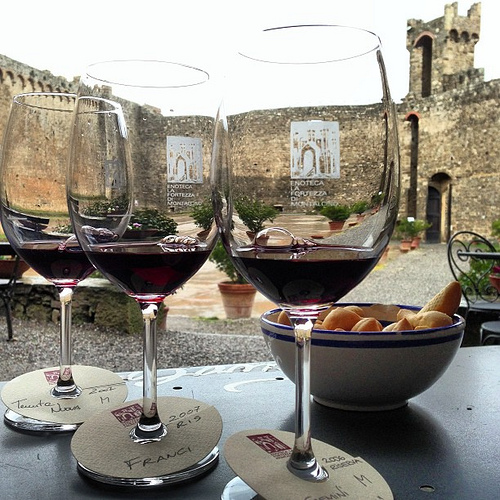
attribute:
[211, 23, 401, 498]
glass — clear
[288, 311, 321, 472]
stem — a handle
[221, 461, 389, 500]
base — the bottom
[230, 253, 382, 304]
wine — liquid, red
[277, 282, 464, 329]
bread — food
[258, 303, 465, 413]
bowl — large, full, white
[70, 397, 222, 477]
paper — circular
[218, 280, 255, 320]
pot — brown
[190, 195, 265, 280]
plant — potted, green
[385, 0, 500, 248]
wall — ancient, in back, huge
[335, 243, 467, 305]
floor — gravel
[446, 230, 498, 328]
chair — iron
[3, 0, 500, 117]
sky — overcast